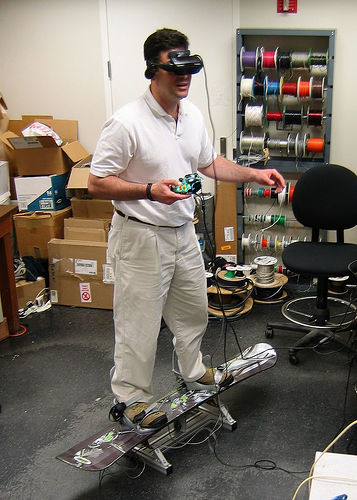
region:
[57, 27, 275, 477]
A man standing on a game snowboard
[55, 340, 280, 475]
A video game snowboard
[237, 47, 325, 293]
Spools of wire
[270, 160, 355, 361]
A black desk chair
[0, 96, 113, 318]
Cardboard boxes in the office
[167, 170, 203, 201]
A green video game controller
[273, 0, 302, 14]
A fire alarm signal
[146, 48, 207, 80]
Virtual reality goggles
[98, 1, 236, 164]
The door leading into the office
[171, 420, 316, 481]
Wires leading from the snowboard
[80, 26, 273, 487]
man playing a virtual reality snowboarding game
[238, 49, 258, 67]
spool of purple wire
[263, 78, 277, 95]
spool of blue wire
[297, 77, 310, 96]
spool of orange wire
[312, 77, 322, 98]
spool of brown wire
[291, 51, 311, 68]
spool of gray wire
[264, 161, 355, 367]
armless swiveling black office chair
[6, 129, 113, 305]
collection of various sized boxes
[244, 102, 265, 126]
spool of white wire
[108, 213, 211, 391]
pair of business casual khaki slacks.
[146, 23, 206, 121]
a man wearing VR glasses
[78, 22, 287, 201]
a man wearing a white shirt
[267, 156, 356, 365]
a black desk chair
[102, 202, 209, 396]
the pants of a man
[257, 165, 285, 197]
the hand of a man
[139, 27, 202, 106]
the head of a man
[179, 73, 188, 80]
the nose of a man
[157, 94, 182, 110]
the neck of a man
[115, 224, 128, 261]
the pocket in a pair of pants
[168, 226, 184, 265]
the zipper in a pair of pants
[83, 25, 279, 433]
Man on a snowboard playing virtual reality games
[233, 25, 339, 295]
Cabinet of spools of wire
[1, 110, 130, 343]
Boxes stacked up on the floor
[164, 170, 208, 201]
Video game controller in the man's hand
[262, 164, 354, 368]
Black office chair to the right of the man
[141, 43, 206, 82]
Video game googles on the man's eyes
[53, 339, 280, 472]
Snowboard the man playing video games is on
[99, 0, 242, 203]
White door behind the man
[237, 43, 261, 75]
Spool of purple wire in the cabinet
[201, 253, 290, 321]
Spools of wire on the floor next to the man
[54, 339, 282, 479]
Skateboard placed on a metal frame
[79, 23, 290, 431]
Man standing on a skateboard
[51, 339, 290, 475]
Cables running from gadget on the feet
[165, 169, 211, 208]
Hand held controller object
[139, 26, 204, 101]
Man wearing a face gear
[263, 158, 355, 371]
Black chair with wheels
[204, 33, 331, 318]
Many rolls of cables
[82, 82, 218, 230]
Short sleeved white shirt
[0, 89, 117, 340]
Many boxes heaped together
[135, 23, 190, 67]
Thick dark long hair